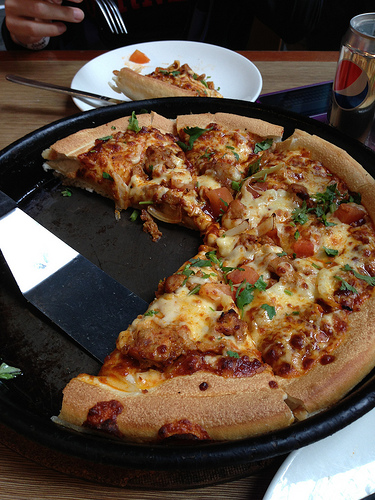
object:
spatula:
[0, 192, 154, 365]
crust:
[53, 371, 298, 443]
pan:
[0, 96, 373, 464]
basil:
[322, 243, 339, 257]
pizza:
[42, 110, 374, 445]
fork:
[93, 1, 131, 36]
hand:
[3, 0, 85, 45]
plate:
[69, 40, 262, 110]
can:
[327, 10, 375, 146]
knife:
[4, 69, 126, 104]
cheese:
[76, 349, 165, 396]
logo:
[329, 60, 370, 113]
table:
[0, 44, 374, 500]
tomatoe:
[291, 235, 314, 259]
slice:
[40, 107, 214, 231]